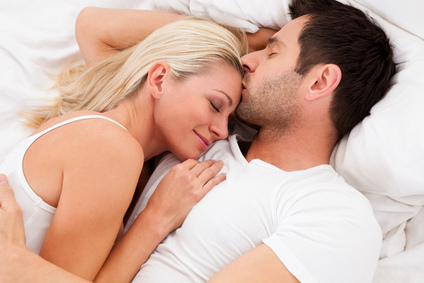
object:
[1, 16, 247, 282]
woman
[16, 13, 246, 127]
hair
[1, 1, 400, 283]
man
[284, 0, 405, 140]
hair